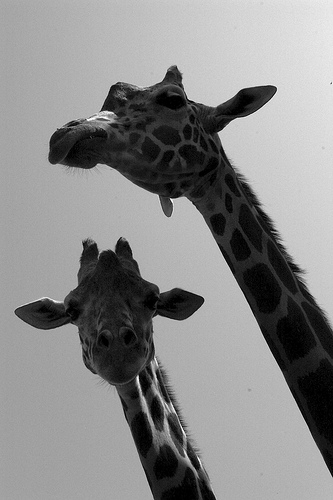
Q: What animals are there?
A: Giraffes.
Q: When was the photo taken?
A: Daytime.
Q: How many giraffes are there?
A: Two.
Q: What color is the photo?
A: Black and white.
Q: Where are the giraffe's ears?
A: On the side of its head.